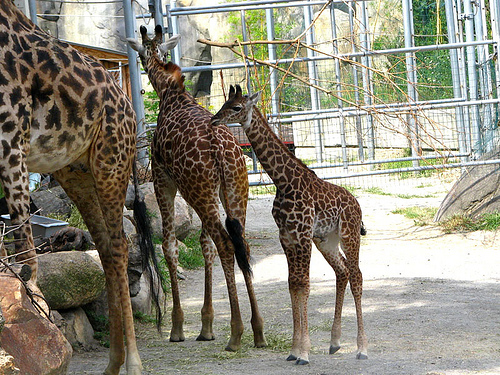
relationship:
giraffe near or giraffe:
[210, 92, 375, 362] [207, 82, 370, 367]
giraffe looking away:
[136, 31, 259, 313] [132, 7, 241, 85]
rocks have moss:
[35, 252, 118, 312] [48, 267, 111, 299]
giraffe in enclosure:
[207, 82, 370, 367] [13, 2, 498, 346]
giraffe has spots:
[210, 92, 375, 362] [292, 179, 344, 223]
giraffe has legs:
[210, 92, 375, 362] [152, 177, 270, 340]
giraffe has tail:
[210, 92, 375, 362] [208, 136, 258, 279]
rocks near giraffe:
[35, 252, 118, 312] [207, 82, 370, 367]